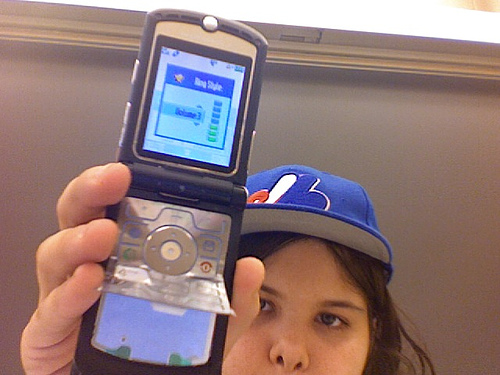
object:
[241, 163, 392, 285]
hat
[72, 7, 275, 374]
phone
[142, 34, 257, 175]
screen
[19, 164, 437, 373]
person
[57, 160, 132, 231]
finger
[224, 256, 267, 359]
thumb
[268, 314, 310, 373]
nose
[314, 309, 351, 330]
eye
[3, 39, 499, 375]
wall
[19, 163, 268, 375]
hand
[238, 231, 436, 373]
hair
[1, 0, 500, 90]
roof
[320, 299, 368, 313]
eyebrow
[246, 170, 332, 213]
logo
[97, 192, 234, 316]
keypad